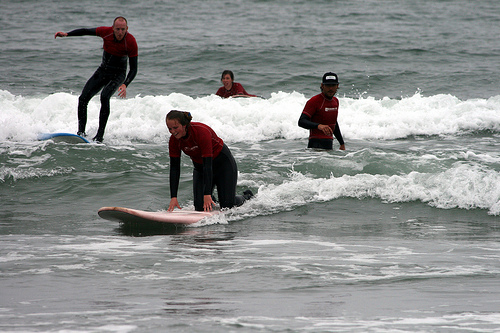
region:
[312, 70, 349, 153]
Man in water wearing baseball cap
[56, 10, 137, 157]
Man standing on blue surfboard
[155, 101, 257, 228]
Woman kneeling on red surfboard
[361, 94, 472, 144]
Large white waves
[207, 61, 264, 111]
Woman in water behind large wave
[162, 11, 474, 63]
Large area of calm water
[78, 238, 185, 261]
White foam on the water surface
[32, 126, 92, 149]
Blue surfboard with white bottom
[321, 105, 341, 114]
White logo on front of red shirt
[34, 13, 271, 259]
Group of surfers on the water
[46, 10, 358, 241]
Four surfers in the shallows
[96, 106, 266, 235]
Lady learning to surf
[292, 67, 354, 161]
surfing coach watching his students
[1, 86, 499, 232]
light waves, perfect for learning to surf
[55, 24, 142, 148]
Red and black surfing suit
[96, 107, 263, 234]
Woman surfing on her kness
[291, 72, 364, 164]
Man standing in shallow water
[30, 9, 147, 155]
Man surfing a small wave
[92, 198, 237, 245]
Light colored surf board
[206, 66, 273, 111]
Beginning surfer trying to catch up to her classmates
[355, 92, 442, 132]
white sea foam on wave top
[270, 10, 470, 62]
small ripples on water surface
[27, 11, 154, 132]
man in black and red wet suit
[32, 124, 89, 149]
tip of blue and white surfboard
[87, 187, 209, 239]
red and black surfboard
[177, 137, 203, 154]
writing on front of red wetsuit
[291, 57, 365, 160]
man in black hat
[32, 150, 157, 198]
small wave on water surface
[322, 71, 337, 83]
white design on front of hat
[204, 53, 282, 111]
woman laying on surfboard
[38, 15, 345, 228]
people surfing in ocean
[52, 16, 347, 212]
people wear red shirts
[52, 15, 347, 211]
people are wearing wetsuits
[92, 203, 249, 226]
woman is on white surfboard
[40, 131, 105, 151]
blue surfboard under man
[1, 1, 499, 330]
blue-green color ocean water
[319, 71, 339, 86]
man has on hat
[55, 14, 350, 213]
two men are in the shot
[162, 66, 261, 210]
two women in shot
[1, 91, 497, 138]
the wave is white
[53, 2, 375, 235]
four people in the ocean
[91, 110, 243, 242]
a woman on a surf board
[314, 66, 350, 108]
a man wearing a hat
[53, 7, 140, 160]
a man on a surf board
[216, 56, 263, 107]
a woman with brown hair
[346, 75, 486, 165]
a wave in the ocean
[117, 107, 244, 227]
a woman on her knees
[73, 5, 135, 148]
a man wearing a wet suit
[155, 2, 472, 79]
a body of water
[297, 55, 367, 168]
a man standing in the water